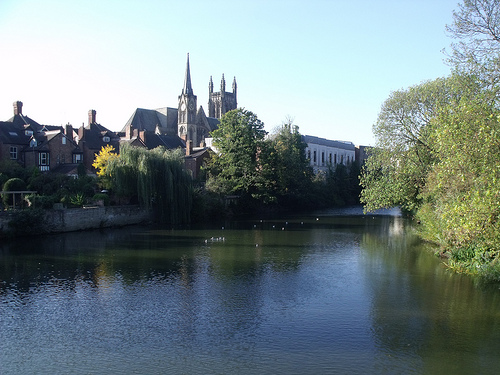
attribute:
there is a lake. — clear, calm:
[0, 202, 499, 372]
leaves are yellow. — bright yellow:
[89, 141, 122, 179]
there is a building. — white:
[302, 133, 357, 185]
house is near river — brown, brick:
[2, 95, 119, 222]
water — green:
[0, 215, 498, 374]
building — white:
[298, 131, 358, 181]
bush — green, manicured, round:
[4, 162, 34, 211]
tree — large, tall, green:
[208, 106, 267, 221]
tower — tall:
[167, 43, 208, 144]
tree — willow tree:
[102, 126, 198, 215]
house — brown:
[2, 94, 122, 190]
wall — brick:
[34, 193, 159, 234]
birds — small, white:
[192, 212, 331, 252]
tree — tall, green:
[442, 3, 484, 74]